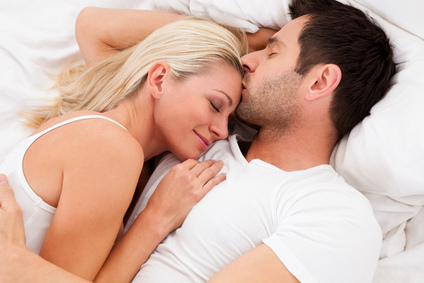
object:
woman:
[1, 16, 247, 282]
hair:
[16, 13, 246, 127]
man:
[1, 1, 400, 283]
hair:
[284, 0, 405, 140]